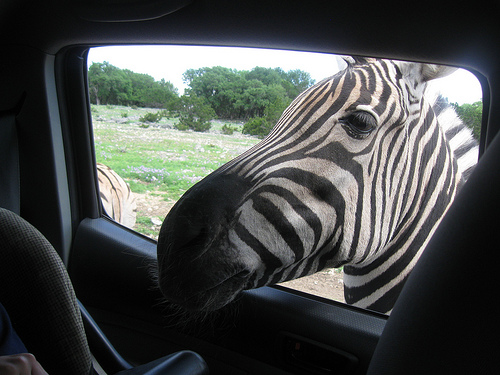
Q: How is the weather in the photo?
A: It is overcast.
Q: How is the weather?
A: It is overcast.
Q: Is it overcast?
A: Yes, it is overcast.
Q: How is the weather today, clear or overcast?
A: It is overcast.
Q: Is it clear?
A: No, it is overcast.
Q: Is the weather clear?
A: No, it is overcast.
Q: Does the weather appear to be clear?
A: No, it is overcast.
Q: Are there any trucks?
A: No, there are no trucks.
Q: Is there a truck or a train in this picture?
A: No, there are no trucks or trains.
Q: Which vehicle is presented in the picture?
A: The vehicle is a car.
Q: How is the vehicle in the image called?
A: The vehicle is a car.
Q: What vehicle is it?
A: The vehicle is a car.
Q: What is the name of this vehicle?
A: This is a car.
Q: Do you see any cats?
A: No, there are no cats.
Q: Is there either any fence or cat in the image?
A: No, there are no cats or fences.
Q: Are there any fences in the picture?
A: No, there are no fences.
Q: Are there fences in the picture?
A: No, there are no fences.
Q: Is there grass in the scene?
A: Yes, there is grass.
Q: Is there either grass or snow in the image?
A: Yes, there is grass.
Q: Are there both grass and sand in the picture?
A: No, there is grass but no sand.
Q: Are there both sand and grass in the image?
A: No, there is grass but no sand.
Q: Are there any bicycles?
A: No, there are no bicycles.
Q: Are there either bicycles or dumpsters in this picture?
A: No, there are no bicycles or dumpsters.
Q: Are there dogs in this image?
A: No, there are no dogs.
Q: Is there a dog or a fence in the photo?
A: No, there are no dogs or fences.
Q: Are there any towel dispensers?
A: No, there are no towel dispensers.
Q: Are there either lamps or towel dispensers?
A: No, there are no towel dispensers or lamps.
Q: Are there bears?
A: No, there are no bears.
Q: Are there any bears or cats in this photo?
A: No, there are no bears or cats.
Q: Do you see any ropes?
A: No, there are no ropes.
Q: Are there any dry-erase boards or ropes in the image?
A: No, there are no ropes or dry-erase boards.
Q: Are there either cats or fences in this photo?
A: No, there are no cats or fences.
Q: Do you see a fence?
A: No, there are no fences.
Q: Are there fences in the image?
A: No, there are no fences.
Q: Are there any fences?
A: No, there are no fences.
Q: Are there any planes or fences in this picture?
A: No, there are no fences or planes.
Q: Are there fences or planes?
A: No, there are no fences or planes.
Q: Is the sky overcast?
A: Yes, the sky is overcast.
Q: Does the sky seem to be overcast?
A: Yes, the sky is overcast.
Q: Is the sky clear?
A: No, the sky is overcast.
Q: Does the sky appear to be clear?
A: No, the sky is overcast.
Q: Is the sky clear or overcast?
A: The sky is overcast.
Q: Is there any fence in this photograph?
A: No, there are no fences.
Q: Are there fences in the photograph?
A: No, there are no fences.